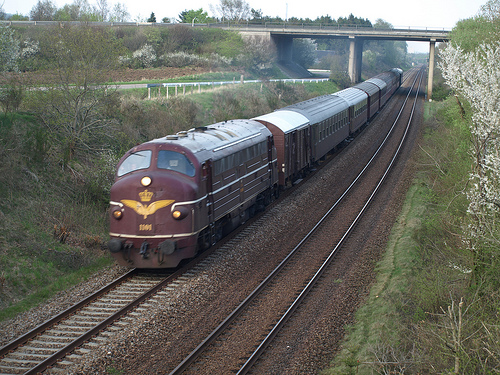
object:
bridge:
[0, 17, 457, 99]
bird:
[119, 198, 175, 220]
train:
[103, 66, 406, 270]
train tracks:
[233, 304, 294, 375]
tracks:
[72, 305, 125, 340]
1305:
[139, 223, 153, 231]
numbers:
[139, 223, 143, 231]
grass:
[318, 68, 500, 375]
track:
[0, 64, 429, 375]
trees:
[0, 10, 129, 171]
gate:
[146, 78, 330, 90]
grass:
[0, 21, 340, 316]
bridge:
[219, 20, 453, 102]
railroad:
[0, 63, 428, 375]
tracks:
[161, 323, 224, 374]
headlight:
[112, 210, 122, 220]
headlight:
[171, 206, 189, 220]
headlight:
[140, 176, 153, 187]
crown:
[138, 188, 154, 202]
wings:
[119, 198, 144, 216]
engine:
[107, 117, 281, 270]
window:
[156, 149, 197, 177]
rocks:
[168, 306, 180, 312]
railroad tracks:
[0, 292, 92, 355]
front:
[105, 140, 210, 270]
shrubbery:
[354, 117, 500, 375]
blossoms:
[478, 89, 493, 98]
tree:
[428, 30, 500, 262]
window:
[116, 149, 152, 177]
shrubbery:
[36, 210, 77, 250]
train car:
[273, 93, 351, 164]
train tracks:
[316, 246, 338, 267]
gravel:
[0, 63, 426, 375]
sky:
[0, 0, 500, 30]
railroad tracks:
[167, 275, 271, 375]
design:
[120, 189, 176, 220]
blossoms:
[461, 70, 469, 80]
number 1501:
[139, 223, 152, 231]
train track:
[0, 266, 184, 375]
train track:
[164, 66, 427, 375]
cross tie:
[0, 320, 132, 375]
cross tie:
[30, 340, 91, 352]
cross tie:
[46, 326, 112, 337]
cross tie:
[70, 312, 129, 326]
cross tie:
[91, 296, 152, 308]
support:
[348, 36, 364, 85]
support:
[426, 38, 437, 101]